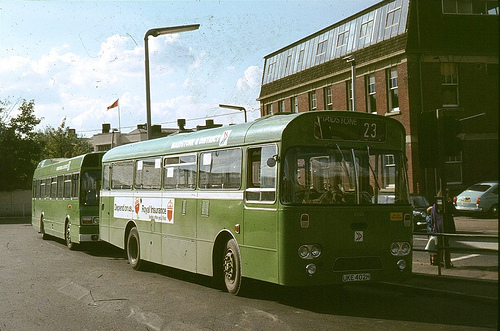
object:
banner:
[113, 196, 176, 224]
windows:
[248, 145, 275, 188]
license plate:
[341, 273, 372, 283]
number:
[363, 122, 370, 138]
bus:
[101, 110, 416, 297]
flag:
[107, 98, 120, 110]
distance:
[71, 49, 134, 72]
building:
[259, 0, 499, 205]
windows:
[364, 75, 377, 116]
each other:
[68, 144, 116, 265]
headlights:
[297, 242, 325, 260]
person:
[425, 179, 463, 268]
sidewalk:
[455, 257, 497, 307]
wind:
[92, 93, 131, 97]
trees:
[0, 100, 81, 195]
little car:
[453, 175, 499, 219]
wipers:
[335, 144, 357, 194]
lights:
[303, 261, 319, 278]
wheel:
[218, 238, 243, 297]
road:
[92, 268, 157, 325]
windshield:
[280, 141, 413, 207]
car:
[409, 193, 438, 232]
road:
[452, 207, 500, 262]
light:
[146, 18, 203, 43]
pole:
[142, 27, 153, 138]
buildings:
[80, 114, 247, 150]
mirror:
[266, 157, 277, 167]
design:
[51, 275, 239, 330]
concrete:
[30, 256, 72, 272]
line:
[447, 251, 482, 263]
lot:
[0, 175, 499, 331]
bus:
[32, 151, 104, 249]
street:
[459, 214, 484, 230]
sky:
[6, 5, 139, 55]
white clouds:
[57, 53, 137, 113]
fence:
[2, 185, 31, 221]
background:
[0, 72, 500, 154]